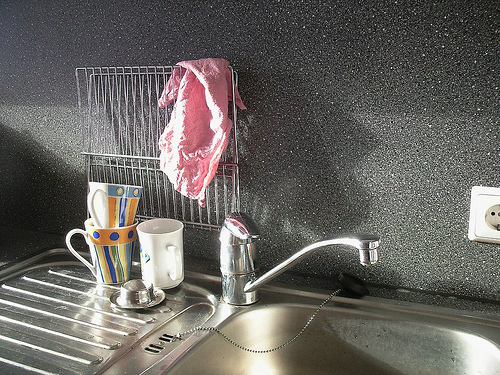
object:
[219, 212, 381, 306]
faucet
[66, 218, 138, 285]
cup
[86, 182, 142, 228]
cup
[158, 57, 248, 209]
cloth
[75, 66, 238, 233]
rack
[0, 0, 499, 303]
wall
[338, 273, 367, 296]
stopper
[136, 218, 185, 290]
cup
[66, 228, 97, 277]
handle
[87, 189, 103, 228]
handle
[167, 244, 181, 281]
handle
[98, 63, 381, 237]
shadow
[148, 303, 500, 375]
sink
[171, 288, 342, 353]
chain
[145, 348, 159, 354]
drain hole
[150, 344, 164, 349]
drain hole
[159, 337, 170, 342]
drain hole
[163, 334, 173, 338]
drain hole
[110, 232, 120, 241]
blue dot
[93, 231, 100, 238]
blue dot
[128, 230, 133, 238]
blue dot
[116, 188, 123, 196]
yellow dot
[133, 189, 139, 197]
yellow dot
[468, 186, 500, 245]
outlet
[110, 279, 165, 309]
lid